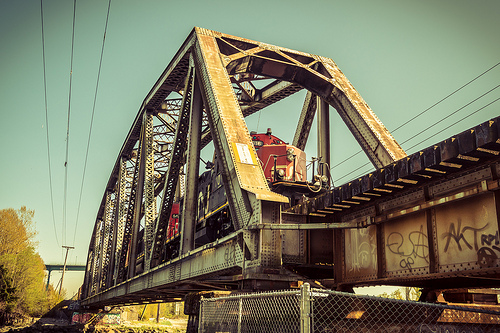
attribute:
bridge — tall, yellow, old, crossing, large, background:
[119, 209, 253, 260]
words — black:
[380, 226, 438, 263]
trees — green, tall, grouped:
[4, 226, 55, 292]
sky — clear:
[328, 9, 391, 34]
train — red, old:
[258, 128, 323, 194]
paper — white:
[234, 150, 253, 164]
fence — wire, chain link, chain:
[213, 296, 251, 311]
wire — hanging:
[91, 1, 116, 73]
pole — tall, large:
[55, 260, 65, 285]